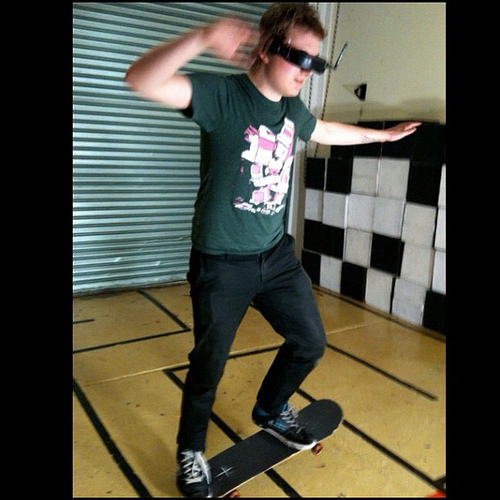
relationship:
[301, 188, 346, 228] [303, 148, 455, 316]
square on wall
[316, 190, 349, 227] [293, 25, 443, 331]
square on wall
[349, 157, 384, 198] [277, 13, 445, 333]
square on wall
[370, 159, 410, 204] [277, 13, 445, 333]
square on wall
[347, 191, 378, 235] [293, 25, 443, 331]
square on wall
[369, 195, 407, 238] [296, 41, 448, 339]
square on wall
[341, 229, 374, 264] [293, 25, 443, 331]
square on wall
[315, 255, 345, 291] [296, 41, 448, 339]
square on wall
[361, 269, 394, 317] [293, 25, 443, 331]
square on wall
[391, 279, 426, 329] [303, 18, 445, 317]
square on wall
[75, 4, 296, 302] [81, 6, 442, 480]
door to garage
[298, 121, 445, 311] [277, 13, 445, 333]
tiles on wall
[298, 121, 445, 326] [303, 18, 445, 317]
tiles on wall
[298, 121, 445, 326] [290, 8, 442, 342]
tiles on wall